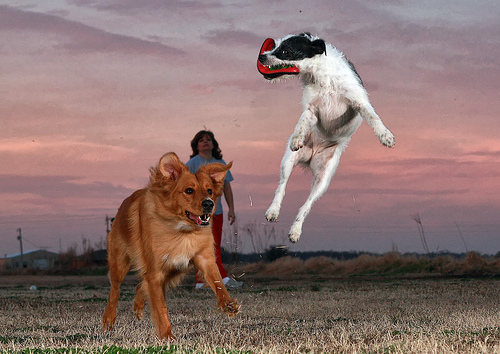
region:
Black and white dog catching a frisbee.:
[237, 12, 400, 127]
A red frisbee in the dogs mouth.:
[240, 17, 345, 91]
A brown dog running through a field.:
[85, 143, 239, 341]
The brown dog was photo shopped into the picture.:
[87, 148, 244, 328]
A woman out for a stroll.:
[174, 102, 251, 291]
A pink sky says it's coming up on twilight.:
[49, 73, 165, 173]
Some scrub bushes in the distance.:
[262, 248, 467, 299]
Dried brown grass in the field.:
[272, 282, 434, 338]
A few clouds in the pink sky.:
[392, 132, 482, 217]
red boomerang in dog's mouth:
[255, 39, 298, 79]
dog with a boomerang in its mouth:
[253, 31, 395, 243]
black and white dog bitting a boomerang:
[261, 28, 393, 241]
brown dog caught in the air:
[102, 152, 241, 337]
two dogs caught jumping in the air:
[101, 34, 394, 336]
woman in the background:
[182, 128, 239, 287]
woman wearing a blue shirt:
[184, 130, 237, 285]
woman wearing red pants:
[181, 129, 236, 289]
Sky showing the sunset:
[0, 3, 497, 251]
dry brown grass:
[0, 270, 499, 351]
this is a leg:
[139, 209, 252, 306]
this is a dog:
[102, 281, 214, 337]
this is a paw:
[129, 303, 237, 334]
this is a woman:
[184, 134, 215, 145]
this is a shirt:
[188, 148, 203, 160]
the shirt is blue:
[172, 151, 240, 171]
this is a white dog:
[263, 81, 360, 214]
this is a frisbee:
[257, 59, 309, 74]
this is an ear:
[132, 127, 177, 174]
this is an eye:
[172, 172, 229, 222]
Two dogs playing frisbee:
[82, 19, 407, 347]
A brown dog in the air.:
[101, 154, 241, 341]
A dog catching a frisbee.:
[257, 29, 394, 244]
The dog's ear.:
[158, 152, 185, 182]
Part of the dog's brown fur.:
[148, 222, 162, 253]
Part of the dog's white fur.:
[326, 69, 348, 89]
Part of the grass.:
[317, 311, 374, 346]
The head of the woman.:
[189, 129, 217, 156]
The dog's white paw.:
[288, 217, 303, 242]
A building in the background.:
[3, 247, 62, 269]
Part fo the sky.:
[82, 59, 145, 124]